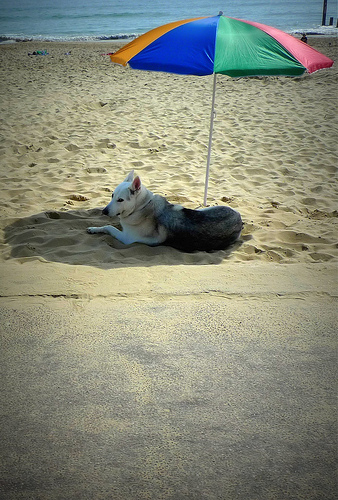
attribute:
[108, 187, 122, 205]
eyes — dog's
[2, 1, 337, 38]
water — dark-blue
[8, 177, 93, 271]
shadow — umbrella's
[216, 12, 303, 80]
stripe — green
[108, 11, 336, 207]
umbrella — multicolored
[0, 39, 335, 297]
beach — sandy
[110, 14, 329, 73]
umbrella — brightly colored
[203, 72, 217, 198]
pole — umbrella's, white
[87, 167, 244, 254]
dog — black-and-white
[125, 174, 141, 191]
ear — dog's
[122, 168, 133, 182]
ear — dog's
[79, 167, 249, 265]
dog — black-and-white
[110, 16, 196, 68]
stripe — yellow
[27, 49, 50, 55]
object — blue